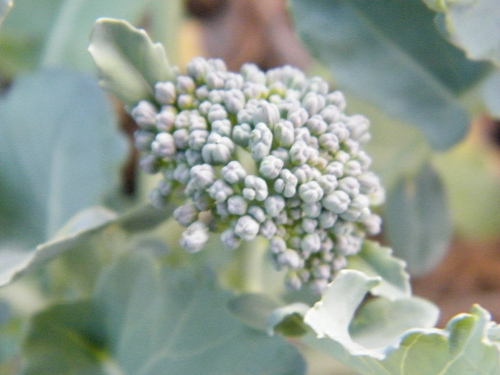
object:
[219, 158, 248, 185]
bud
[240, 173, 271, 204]
bud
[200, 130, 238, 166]
bud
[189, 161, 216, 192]
bud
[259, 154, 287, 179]
bud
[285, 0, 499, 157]
leaf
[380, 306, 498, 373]
leaf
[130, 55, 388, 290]
plant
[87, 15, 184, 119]
leaf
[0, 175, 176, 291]
leaves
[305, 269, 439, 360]
plant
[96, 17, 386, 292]
vegetable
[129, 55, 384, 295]
broccoli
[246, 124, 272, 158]
floret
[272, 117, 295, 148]
florets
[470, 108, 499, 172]
flowers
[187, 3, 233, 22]
person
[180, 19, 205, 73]
dress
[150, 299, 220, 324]
velvety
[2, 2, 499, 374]
photo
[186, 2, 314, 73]
background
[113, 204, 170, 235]
shadows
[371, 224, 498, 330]
ground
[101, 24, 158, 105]
line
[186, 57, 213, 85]
bud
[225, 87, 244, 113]
bud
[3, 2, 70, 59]
green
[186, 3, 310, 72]
area